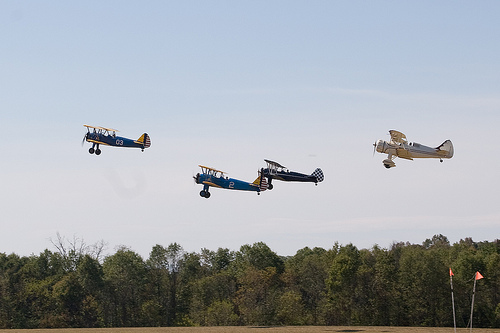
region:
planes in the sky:
[77, 102, 467, 204]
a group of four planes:
[68, 110, 468, 210]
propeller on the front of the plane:
[370, 135, 380, 155]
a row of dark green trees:
[0, 229, 499, 331]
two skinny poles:
[444, 257, 488, 331]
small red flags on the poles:
[443, 263, 492, 323]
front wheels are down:
[198, 185, 210, 199]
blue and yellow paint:
[188, 160, 270, 207]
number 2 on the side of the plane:
[226, 178, 236, 192]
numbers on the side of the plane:
[113, 136, 125, 150]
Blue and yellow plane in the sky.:
[190, 175, 214, 197]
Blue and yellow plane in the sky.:
[225, 177, 229, 187]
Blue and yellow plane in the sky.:
[269, 162, 278, 174]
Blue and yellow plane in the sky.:
[77, 109, 154, 166]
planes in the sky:
[72, 106, 459, 206]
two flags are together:
[435, 270, 485, 332]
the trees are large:
[95, 266, 379, 321]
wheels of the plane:
[187, 186, 211, 201]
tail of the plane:
[426, 133, 450, 153]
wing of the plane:
[384, 129, 416, 145]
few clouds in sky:
[346, 205, 388, 225]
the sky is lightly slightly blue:
[415, 202, 447, 237]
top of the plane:
[80, 121, 117, 134]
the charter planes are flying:
[45, 71, 467, 219]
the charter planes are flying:
[57, 111, 467, 205]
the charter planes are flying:
[60, 102, 495, 219]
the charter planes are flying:
[62, 106, 480, 226]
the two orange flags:
[432, 259, 497, 289]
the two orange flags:
[436, 255, 495, 293]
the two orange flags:
[440, 254, 490, 294]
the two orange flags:
[425, 254, 497, 281]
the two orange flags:
[423, 255, 498, 310]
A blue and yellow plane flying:
[76, 118, 162, 159]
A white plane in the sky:
[371, 128, 461, 171]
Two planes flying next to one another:
[185, 154, 333, 199]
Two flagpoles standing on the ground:
[447, 263, 483, 332]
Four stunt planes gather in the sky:
[81, 122, 456, 200]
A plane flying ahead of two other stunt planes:
[75, 120, 326, 200]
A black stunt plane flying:
[255, 155, 327, 190]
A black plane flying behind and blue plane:
[188, 153, 325, 203]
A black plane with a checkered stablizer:
[253, 156, 329, 188]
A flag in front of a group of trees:
[467, 269, 488, 331]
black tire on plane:
[88, 145, 95, 156]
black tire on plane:
[95, 148, 100, 159]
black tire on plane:
[203, 192, 212, 198]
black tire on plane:
[199, 188, 206, 200]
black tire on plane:
[266, 182, 271, 192]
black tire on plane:
[382, 159, 389, 169]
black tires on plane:
[90, 145, 102, 159]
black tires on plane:
[196, 188, 211, 200]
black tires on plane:
[266, 178, 274, 190]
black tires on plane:
[384, 160, 391, 170]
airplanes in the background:
[52, 80, 497, 205]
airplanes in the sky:
[46, 72, 487, 238]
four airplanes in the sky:
[39, 54, 487, 191]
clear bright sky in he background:
[37, 36, 469, 258]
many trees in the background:
[25, 222, 497, 329]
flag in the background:
[410, 256, 497, 325]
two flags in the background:
[424, 262, 495, 314]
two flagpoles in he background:
[416, 249, 496, 320]